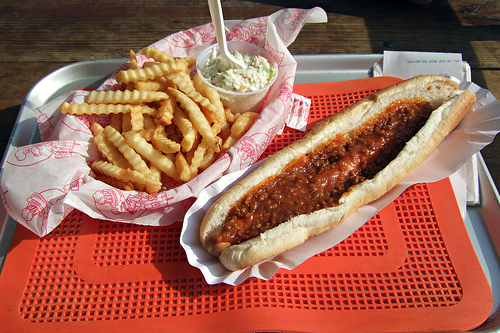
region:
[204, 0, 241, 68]
a plastic fork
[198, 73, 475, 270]
a hot dog bun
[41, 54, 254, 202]
french fries in the basket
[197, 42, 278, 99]
a cup of cole slaw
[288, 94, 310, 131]
single serving salt packet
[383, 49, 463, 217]
paper receipt on the tray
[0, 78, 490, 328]
red rubber mat under the food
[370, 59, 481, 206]
stack of white napkins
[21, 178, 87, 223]
red pattern on the paper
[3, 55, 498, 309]
metal tray to carry the food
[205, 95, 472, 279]
chili dog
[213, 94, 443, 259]
hot dog with chili on top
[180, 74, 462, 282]
hot dog on a piece of paper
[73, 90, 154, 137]
french fries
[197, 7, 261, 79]
white plastic fork in food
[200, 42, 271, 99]
plastic ramekin filled with food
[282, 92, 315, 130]
salt packet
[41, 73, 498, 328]
food is on a metal tray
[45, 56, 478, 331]
food is on a red mat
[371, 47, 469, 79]
receipt with black text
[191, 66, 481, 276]
foot long chili hot dog sandwich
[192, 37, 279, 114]
small container of cole slaw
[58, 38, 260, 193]
golden crinkle cut french fries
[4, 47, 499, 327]
silver rectangular tray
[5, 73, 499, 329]
perforated red rubber matt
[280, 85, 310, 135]
red and white salt packet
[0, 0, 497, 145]
dark brown wooden picnic table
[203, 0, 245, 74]
white plastic disposable fork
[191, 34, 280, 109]
small white plastic ramikin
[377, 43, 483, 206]
receipt paper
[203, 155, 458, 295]
a hot dog with chili on a bun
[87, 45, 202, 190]
french fries in a bowl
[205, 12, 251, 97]
small bowl of cole slaw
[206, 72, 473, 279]
a hot dog on a bun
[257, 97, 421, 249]
chili on a hot dog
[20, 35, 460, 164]
a metal tray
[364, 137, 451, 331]
orange place mat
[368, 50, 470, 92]
a paper reciept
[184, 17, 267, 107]
a plastic fork in a bowl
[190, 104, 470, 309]
a hot dog bun